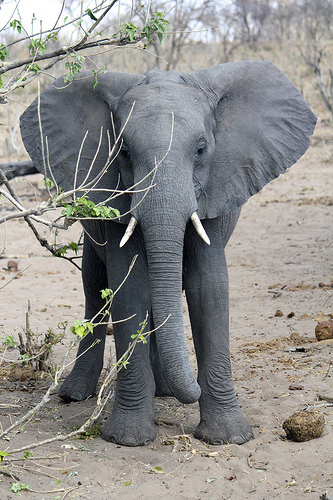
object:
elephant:
[18, 59, 317, 447]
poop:
[281, 410, 325, 442]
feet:
[189, 408, 252, 448]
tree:
[1, 0, 218, 488]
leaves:
[1, 1, 171, 468]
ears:
[199, 60, 318, 226]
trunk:
[141, 213, 202, 404]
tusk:
[190, 211, 215, 247]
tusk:
[118, 216, 137, 249]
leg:
[185, 248, 255, 447]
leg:
[102, 224, 159, 445]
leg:
[149, 314, 178, 398]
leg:
[59, 238, 111, 402]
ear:
[18, 69, 138, 226]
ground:
[1, 35, 333, 499]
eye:
[194, 140, 208, 156]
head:
[110, 70, 218, 229]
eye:
[116, 141, 131, 155]